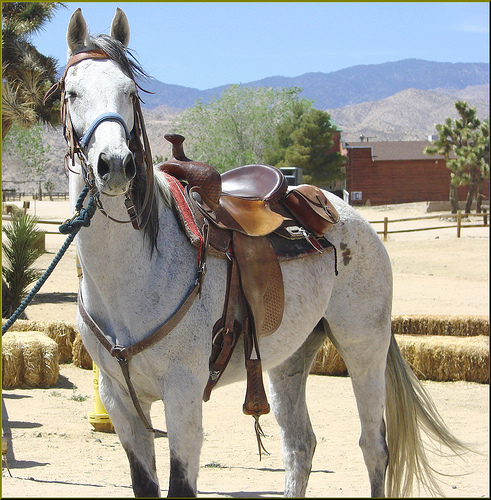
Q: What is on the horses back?
A: Saddle.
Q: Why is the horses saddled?
A: To ride.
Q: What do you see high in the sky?
A: Nothing.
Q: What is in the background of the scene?
A: Mountains.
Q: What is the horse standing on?
A: Dirt.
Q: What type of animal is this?
A: Horse.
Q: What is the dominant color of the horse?
A: White.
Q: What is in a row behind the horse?
A: Hay.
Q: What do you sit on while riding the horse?
A: Saddle.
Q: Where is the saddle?
A: Back.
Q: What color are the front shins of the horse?
A: Black.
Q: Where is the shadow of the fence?
A: Bottom left.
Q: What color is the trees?
A: Green.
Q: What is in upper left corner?
A: Palm tree.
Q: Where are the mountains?
A: In the distance.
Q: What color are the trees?
A: Green.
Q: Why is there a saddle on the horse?
A: To ride.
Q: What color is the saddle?
A: Brown.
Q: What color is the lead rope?
A: Blue.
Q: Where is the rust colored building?
A: Background.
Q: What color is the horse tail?
A: White, black mix.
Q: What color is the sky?
A: Blue.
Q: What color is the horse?
A: White.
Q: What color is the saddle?
A: Brown.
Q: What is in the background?
A: A barn.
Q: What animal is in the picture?
A: Horse.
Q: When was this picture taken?
A: Daytime.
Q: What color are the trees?
A: Green.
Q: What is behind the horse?
A: Hay.